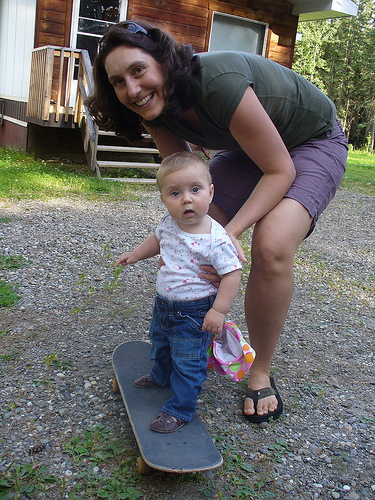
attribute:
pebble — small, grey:
[323, 492, 342, 498]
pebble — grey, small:
[302, 340, 371, 476]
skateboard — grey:
[132, 339, 189, 430]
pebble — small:
[274, 472, 293, 490]